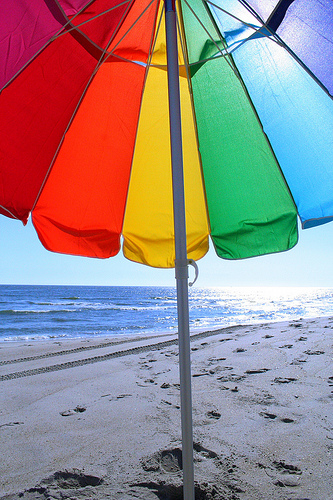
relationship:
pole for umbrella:
[160, 0, 196, 499] [0, 7, 332, 272]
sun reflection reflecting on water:
[235, 286, 295, 320] [6, 286, 293, 325]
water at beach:
[0, 282, 330, 343] [1, 276, 330, 498]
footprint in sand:
[273, 375, 297, 384] [1, 316, 332, 499]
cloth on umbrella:
[117, 0, 212, 271] [0, 7, 332, 272]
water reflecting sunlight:
[0, 282, 330, 343] [188, 279, 331, 321]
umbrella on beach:
[0, 7, 332, 272] [1, 276, 330, 498]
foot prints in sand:
[20, 431, 323, 499] [31, 447, 332, 499]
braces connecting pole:
[36, 0, 291, 59] [151, 2, 214, 498]